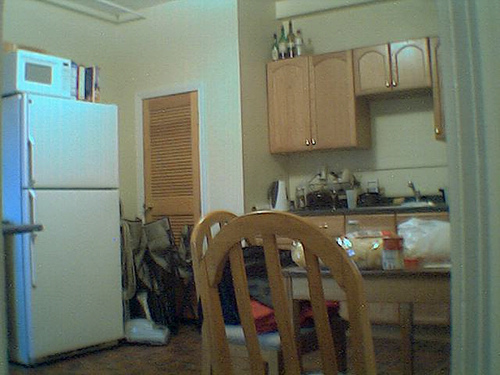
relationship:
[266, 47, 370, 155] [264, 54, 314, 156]
cupboard with door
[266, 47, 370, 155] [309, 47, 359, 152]
cupboard with door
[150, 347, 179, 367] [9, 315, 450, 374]
part of floor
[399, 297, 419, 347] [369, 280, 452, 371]
part of stand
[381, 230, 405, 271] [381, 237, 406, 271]
can of food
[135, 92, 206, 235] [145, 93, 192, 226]
door sheilding water heater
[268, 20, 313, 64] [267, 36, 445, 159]
alcohol on top of cabinets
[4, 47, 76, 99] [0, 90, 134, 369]
microwave on top of refrigerator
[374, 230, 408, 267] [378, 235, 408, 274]
can of food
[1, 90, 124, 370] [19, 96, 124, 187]
fridge and freezer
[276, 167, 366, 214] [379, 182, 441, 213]
clutter next to sink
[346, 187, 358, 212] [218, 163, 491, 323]
cup on counter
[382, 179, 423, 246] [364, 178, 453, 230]
sponge beside sink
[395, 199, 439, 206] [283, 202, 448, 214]
sink built into counter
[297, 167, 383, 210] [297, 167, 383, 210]
clutter in clutter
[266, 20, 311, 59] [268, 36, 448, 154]
bottle on cupboard